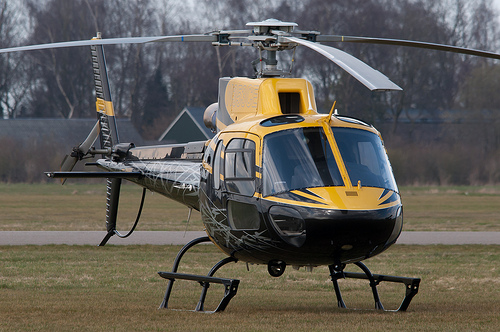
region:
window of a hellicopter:
[246, 119, 345, 196]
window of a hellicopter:
[331, 123, 413, 195]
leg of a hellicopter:
[316, 257, 433, 317]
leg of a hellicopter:
[143, 249, 250, 329]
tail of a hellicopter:
[72, 125, 216, 216]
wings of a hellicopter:
[8, 12, 499, 97]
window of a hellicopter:
[213, 139, 263, 182]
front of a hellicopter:
[292, 183, 407, 258]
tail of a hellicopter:
[69, 31, 136, 253]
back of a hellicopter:
[118, 146, 217, 199]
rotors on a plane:
[137, 18, 404, 105]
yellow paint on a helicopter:
[228, 75, 312, 113]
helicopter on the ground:
[38, 86, 435, 330]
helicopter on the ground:
[157, 118, 312, 305]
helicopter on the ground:
[266, 42, 428, 315]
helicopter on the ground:
[55, 38, 205, 277]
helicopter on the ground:
[255, 76, 381, 316]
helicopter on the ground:
[208, 60, 335, 327]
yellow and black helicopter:
[48, 16, 461, 305]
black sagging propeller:
[288, 16, 400, 108]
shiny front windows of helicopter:
[261, 124, 408, 203]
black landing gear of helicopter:
[152, 250, 252, 318]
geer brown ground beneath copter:
[37, 240, 132, 325]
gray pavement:
[23, 220, 89, 252]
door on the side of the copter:
[218, 130, 265, 242]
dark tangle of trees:
[419, 76, 488, 176]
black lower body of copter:
[195, 185, 427, 274]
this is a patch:
[93, 249, 141, 301]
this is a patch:
[403, 242, 467, 300]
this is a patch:
[29, 188, 89, 216]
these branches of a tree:
[383, 3, 464, 120]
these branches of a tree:
[120, 25, 191, 109]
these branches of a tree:
[10, 8, 81, 118]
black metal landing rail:
[171, 249, 214, 301]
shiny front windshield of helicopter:
[264, 134, 306, 182]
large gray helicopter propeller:
[356, 55, 369, 87]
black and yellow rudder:
[76, 78, 112, 110]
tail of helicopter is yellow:
[98, 96, 125, 149]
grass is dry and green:
[52, 257, 77, 297]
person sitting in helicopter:
[303, 140, 364, 184]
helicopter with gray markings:
[161, 157, 190, 182]